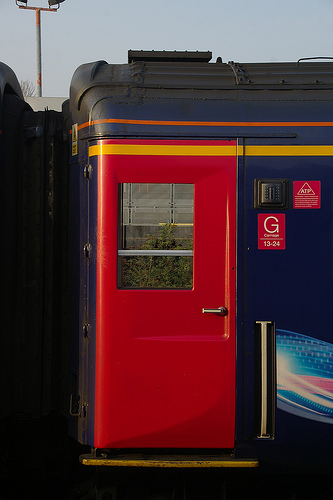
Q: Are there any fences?
A: No, there are no fences.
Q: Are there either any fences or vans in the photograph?
A: No, there are no fences or vans.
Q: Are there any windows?
A: Yes, there is a window.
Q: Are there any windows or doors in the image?
A: Yes, there is a window.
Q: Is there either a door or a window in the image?
A: Yes, there is a window.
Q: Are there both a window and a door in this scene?
A: Yes, there are both a window and a door.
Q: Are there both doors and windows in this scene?
A: Yes, there are both a window and a door.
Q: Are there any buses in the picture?
A: No, there are no buses.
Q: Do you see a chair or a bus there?
A: No, there are no buses or chairs.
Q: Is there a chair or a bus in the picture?
A: No, there are no buses or chairs.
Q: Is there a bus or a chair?
A: No, there are no buses or chairs.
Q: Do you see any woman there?
A: Yes, there is a woman.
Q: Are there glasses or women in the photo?
A: Yes, there is a woman.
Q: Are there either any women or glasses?
A: Yes, there is a woman.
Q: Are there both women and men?
A: No, there is a woman but no men.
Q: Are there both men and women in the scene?
A: No, there is a woman but no men.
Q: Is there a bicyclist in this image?
A: No, there are no cyclists.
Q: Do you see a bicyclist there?
A: No, there are no cyclists.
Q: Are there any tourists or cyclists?
A: No, there are no cyclists or tourists.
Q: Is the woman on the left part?
A: Yes, the woman is on the left of the image.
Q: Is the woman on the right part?
A: No, the woman is on the left of the image.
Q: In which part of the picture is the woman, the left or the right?
A: The woman is on the left of the image.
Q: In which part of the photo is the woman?
A: The woman is on the left of the image.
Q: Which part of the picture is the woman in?
A: The woman is on the left of the image.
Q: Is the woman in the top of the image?
A: Yes, the woman is in the top of the image.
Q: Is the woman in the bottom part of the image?
A: No, the woman is in the top of the image.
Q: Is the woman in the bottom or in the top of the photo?
A: The woman is in the top of the image.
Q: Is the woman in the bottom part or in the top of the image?
A: The woman is in the top of the image.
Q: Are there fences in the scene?
A: No, there are no fences.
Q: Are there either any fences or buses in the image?
A: No, there are no fences or buses.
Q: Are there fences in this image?
A: No, there are no fences.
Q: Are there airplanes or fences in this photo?
A: No, there are no fences or airplanes.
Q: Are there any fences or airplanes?
A: No, there are no fences or airplanes.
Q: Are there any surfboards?
A: No, there are no surfboards.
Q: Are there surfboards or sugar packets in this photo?
A: No, there are no surfboards or sugar packets.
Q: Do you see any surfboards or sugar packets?
A: No, there are no surfboards or sugar packets.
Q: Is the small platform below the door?
A: Yes, the platform is below the door.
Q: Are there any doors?
A: Yes, there is a door.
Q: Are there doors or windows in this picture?
A: Yes, there is a door.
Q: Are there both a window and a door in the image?
A: Yes, there are both a door and a window.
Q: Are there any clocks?
A: No, there are no clocks.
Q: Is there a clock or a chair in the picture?
A: No, there are no clocks or chairs.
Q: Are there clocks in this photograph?
A: No, there are no clocks.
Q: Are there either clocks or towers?
A: No, there are no clocks or towers.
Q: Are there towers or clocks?
A: No, there are no clocks or towers.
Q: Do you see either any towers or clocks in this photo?
A: No, there are no clocks or towers.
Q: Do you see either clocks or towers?
A: No, there are no clocks or towers.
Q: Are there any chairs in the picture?
A: No, there are no chairs.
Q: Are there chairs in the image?
A: No, there are no chairs.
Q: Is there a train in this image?
A: Yes, there is a train.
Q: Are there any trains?
A: Yes, there is a train.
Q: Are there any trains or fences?
A: Yes, there is a train.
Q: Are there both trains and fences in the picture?
A: No, there is a train but no fences.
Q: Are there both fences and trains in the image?
A: No, there is a train but no fences.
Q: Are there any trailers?
A: No, there are no trailers.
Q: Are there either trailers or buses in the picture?
A: No, there are no trailers or buses.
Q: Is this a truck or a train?
A: This is a train.